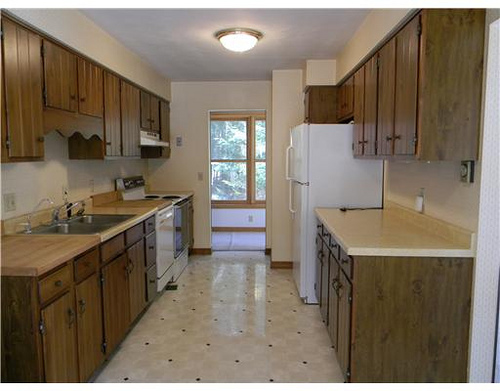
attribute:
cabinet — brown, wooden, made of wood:
[2, 18, 48, 160]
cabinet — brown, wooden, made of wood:
[40, 34, 80, 117]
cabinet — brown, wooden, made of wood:
[101, 68, 125, 159]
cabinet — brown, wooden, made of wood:
[74, 55, 108, 124]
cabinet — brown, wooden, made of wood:
[118, 77, 144, 159]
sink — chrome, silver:
[19, 221, 123, 236]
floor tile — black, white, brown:
[90, 249, 341, 380]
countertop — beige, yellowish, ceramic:
[315, 196, 475, 257]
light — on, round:
[214, 29, 264, 54]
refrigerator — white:
[285, 122, 384, 302]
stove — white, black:
[115, 174, 188, 282]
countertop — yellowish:
[88, 187, 174, 215]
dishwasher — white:
[155, 200, 175, 293]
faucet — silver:
[49, 199, 80, 224]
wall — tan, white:
[382, 157, 481, 234]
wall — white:
[2, 126, 146, 219]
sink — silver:
[57, 211, 144, 226]